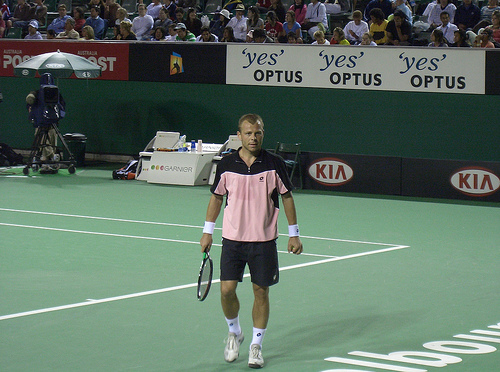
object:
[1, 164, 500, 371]
court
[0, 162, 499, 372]
field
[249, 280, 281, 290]
shorts edge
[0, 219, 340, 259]
line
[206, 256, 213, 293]
racket edge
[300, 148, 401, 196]
banner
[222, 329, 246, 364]
tennis shoes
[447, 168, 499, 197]
kia sign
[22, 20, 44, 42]
people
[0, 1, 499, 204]
stands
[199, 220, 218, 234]
wrist band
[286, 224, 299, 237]
wrist band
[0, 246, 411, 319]
markings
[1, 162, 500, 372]
tennis court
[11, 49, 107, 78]
umbrella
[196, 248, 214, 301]
tennis racket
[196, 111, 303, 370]
man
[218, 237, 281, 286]
shorts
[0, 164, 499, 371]
playing ground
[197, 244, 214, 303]
racket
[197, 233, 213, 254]
man's hand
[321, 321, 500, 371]
writing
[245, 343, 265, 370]
shoes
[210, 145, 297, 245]
shirt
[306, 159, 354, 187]
advertisment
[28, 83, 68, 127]
camera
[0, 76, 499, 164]
barrier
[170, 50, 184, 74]
sign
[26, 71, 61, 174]
person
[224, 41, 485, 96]
banner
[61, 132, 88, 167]
garbage can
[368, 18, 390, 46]
shirt